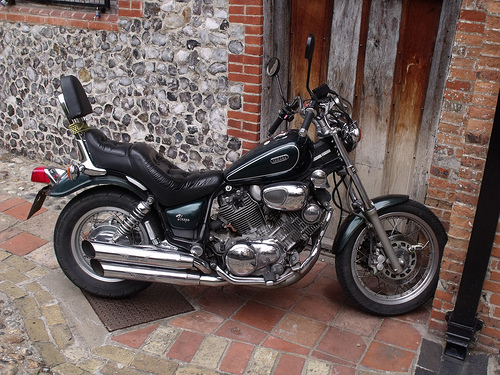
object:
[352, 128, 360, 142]
headlight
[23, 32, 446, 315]
bike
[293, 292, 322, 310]
ground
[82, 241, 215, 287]
exhaust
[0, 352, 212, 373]
ground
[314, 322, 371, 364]
brick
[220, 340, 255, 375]
brick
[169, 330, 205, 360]
brick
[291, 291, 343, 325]
brick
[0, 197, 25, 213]
brick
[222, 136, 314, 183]
fuel tank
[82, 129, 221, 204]
seat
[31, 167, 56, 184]
red light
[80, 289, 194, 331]
mat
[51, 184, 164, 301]
tire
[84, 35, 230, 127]
wall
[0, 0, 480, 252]
building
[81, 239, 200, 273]
exhaust pipes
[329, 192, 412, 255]
fender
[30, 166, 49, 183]
light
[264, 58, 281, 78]
mirrors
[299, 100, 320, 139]
handlebars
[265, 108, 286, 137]
handlebar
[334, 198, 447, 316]
tire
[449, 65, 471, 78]
brick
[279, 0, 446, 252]
door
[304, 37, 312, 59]
mirrors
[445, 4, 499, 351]
wall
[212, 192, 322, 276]
engine